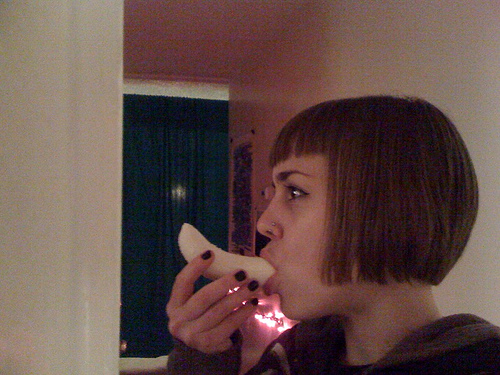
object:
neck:
[343, 280, 442, 365]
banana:
[178, 223, 278, 288]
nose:
[257, 194, 285, 240]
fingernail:
[202, 250, 212, 260]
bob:
[269, 94, 478, 287]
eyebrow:
[276, 170, 310, 181]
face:
[256, 153, 330, 321]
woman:
[165, 95, 500, 375]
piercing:
[272, 222, 277, 226]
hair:
[268, 95, 480, 287]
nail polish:
[250, 298, 258, 306]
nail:
[234, 271, 246, 282]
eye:
[287, 185, 309, 202]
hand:
[165, 250, 260, 350]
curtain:
[118, 93, 231, 358]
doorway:
[119, 93, 230, 360]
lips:
[260, 250, 279, 296]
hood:
[294, 313, 500, 374]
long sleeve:
[166, 331, 243, 375]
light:
[226, 286, 299, 333]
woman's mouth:
[260, 249, 278, 297]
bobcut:
[268, 92, 478, 287]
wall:
[1, 0, 125, 375]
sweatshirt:
[166, 313, 499, 375]